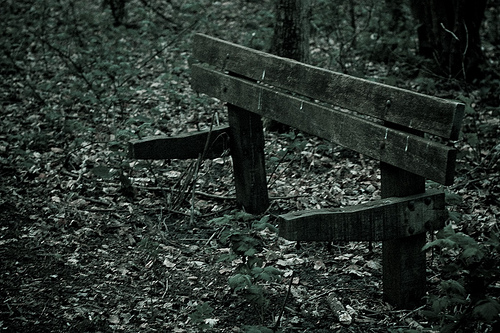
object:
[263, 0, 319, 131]
tree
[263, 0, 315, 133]
trunk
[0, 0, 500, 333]
woods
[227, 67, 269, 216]
pole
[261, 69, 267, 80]
mark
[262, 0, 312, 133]
bark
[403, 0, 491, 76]
tree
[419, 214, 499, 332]
plant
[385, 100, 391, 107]
bolts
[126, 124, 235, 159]
wood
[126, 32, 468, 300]
bench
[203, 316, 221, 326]
leaves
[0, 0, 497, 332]
ground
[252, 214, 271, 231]
leaves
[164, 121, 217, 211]
branches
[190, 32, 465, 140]
slats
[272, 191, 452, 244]
wood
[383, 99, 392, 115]
lag bolt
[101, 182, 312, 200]
stick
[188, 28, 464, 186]
seat back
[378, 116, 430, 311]
pole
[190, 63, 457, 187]
slat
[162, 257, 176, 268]
leaf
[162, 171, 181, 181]
leaf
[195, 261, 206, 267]
leaf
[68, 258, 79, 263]
leaf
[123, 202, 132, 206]
leaf